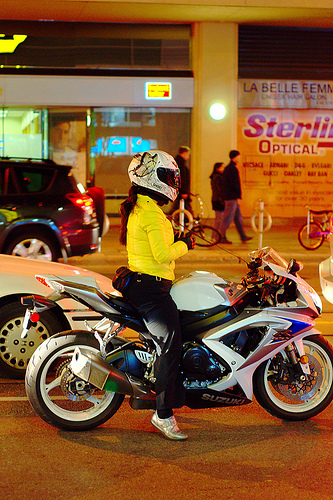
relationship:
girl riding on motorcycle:
[126, 151, 192, 446] [24, 261, 331, 420]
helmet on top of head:
[124, 148, 181, 203] [127, 147, 183, 209]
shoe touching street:
[148, 408, 188, 443] [0, 271, 332, 499]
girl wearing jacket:
[126, 151, 192, 446] [124, 191, 188, 282]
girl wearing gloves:
[126, 151, 192, 446] [173, 228, 197, 253]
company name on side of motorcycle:
[199, 390, 245, 406] [24, 261, 331, 420]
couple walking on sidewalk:
[208, 146, 254, 247] [98, 224, 332, 260]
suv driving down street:
[0, 154, 104, 263] [0, 271, 332, 499]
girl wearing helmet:
[126, 151, 192, 446] [124, 148, 181, 203]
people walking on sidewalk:
[171, 143, 254, 247] [98, 224, 332, 260]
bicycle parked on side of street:
[169, 194, 221, 249] [0, 271, 332, 499]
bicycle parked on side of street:
[295, 205, 332, 249] [0, 271, 332, 499]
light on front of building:
[207, 99, 228, 123] [1, 1, 332, 228]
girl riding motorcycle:
[126, 151, 192, 446] [24, 261, 331, 420]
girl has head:
[126, 151, 192, 446] [127, 147, 183, 209]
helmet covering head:
[124, 148, 181, 203] [127, 147, 183, 209]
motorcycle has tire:
[24, 261, 331, 420] [25, 328, 125, 432]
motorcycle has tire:
[24, 261, 331, 420] [250, 327, 332, 421]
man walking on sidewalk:
[173, 146, 195, 225] [98, 224, 332, 260]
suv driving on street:
[0, 154, 104, 263] [0, 271, 332, 499]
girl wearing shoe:
[126, 151, 192, 446] [148, 408, 188, 443]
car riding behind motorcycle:
[0, 253, 122, 379] [24, 261, 331, 420]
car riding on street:
[0, 253, 122, 379] [0, 271, 332, 499]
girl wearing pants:
[126, 151, 192, 446] [120, 271, 186, 413]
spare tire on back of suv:
[86, 185, 107, 237] [0, 154, 104, 263]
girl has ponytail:
[126, 151, 192, 446] [116, 182, 140, 249]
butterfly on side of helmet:
[130, 151, 159, 180] [124, 148, 181, 203]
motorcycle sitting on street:
[24, 261, 331, 420] [0, 271, 332, 499]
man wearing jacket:
[173, 146, 195, 225] [172, 155, 191, 200]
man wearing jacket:
[219, 149, 254, 245] [222, 160, 243, 202]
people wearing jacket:
[212, 162, 225, 239] [209, 168, 224, 210]